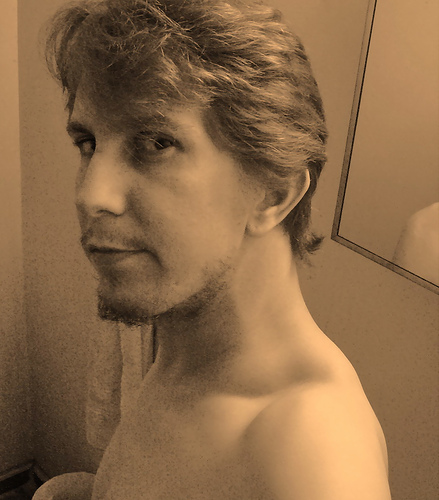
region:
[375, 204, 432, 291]
reflection in the mirror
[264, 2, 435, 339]
mirror on the wall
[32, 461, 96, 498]
toilet in the corner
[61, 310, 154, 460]
curtain on the wall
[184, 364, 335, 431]
shadow on the man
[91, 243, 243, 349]
beard on the mans face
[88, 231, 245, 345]
jaw of the man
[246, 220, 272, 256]
ear lobe on the man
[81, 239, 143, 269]
lips on the man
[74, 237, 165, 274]
mouth of the man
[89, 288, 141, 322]
hair on mans chin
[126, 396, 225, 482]
man wearing no shirt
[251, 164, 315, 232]
the mans ear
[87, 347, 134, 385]
a towel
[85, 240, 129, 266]
the mans lips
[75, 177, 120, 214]
the mans nose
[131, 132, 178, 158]
the mans eye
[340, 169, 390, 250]
a mirror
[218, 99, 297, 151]
the mans hair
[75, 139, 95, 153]
the mans right eye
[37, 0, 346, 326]
man with feathered hair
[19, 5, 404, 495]
man taking a selfie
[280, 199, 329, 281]
small tail of hair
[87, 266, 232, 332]
scraggly beard on a guys chin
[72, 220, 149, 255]
thin sparse mustach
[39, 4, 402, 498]
man with no shirt on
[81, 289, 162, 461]
a towel hanging on the wall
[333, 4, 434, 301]
metal bordered medicine cabinet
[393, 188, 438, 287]
reflection of a body part in the mirror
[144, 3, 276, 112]
light shining on a guys hair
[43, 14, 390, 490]
shirtless man standing in bathroom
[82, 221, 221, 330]
facial hair of man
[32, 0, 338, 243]
blonde hair of man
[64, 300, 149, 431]
shower curtain behind man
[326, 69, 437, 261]
mirror on bathroom wall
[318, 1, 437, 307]
frame of mirror on wall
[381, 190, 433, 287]
man's reflection in mirror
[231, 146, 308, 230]
ear of the man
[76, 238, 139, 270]
lips of the man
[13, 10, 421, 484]
black and white photograph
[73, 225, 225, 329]
man with facial hair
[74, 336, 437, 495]
man wearing no shirt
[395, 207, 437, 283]
reflection of man's shoulder in mirror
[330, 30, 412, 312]
mirror hung on the wall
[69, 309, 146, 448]
towel hanging on the wall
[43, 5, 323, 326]
man looking directly at camera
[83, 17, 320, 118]
man with short wavy hair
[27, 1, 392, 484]
man taking a selfie in the bathroom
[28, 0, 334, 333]
man facing straight but looking to the side